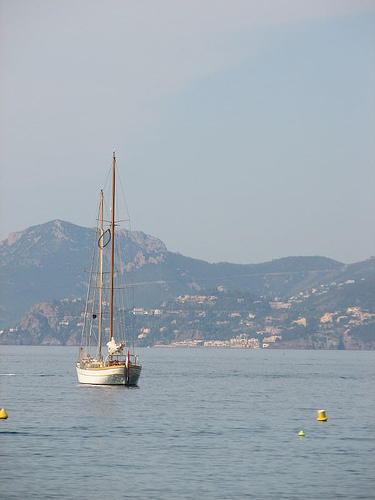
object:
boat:
[74, 148, 141, 387]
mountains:
[0, 217, 374, 352]